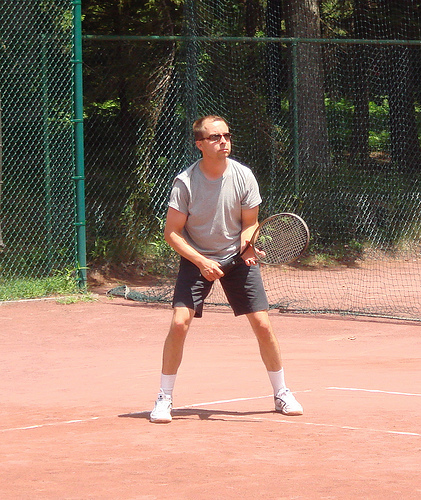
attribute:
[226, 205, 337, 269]
racket — black, white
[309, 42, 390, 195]
fences —  group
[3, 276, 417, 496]
court — light red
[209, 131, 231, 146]
sunglasses — dark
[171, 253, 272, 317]
shorts — black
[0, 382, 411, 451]
lines — white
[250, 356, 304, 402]
socks — white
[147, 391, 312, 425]
shoe — white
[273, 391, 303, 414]
shoe —  pair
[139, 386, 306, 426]
shoes — black, white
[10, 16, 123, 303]
fence — green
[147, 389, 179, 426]
shoe — white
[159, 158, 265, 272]
shirt — gray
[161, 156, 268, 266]
shirt — gray